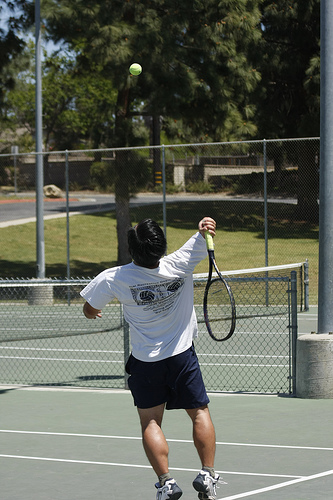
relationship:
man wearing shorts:
[80, 217, 227, 500] [125, 342, 209, 410]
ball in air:
[126, 60, 143, 78] [26, 14, 229, 131]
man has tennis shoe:
[80, 217, 227, 500] [194, 467, 217, 498]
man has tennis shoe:
[80, 217, 227, 500] [147, 473, 181, 498]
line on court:
[251, 412, 299, 466] [17, 397, 115, 495]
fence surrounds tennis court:
[0, 267, 330, 384] [0, 385, 332, 496]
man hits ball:
[80, 217, 227, 500] [113, 43, 160, 86]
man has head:
[80, 217, 227, 500] [120, 207, 190, 263]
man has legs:
[80, 217, 227, 500] [132, 387, 225, 498]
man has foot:
[74, 220, 270, 498] [184, 459, 231, 499]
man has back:
[74, 220, 270, 498] [117, 272, 194, 358]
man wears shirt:
[80, 217, 227, 500] [78, 234, 213, 362]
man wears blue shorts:
[80, 217, 227, 500] [117, 342, 216, 411]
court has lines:
[1, 299, 331, 498] [0, 426, 331, 480]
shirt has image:
[79, 232, 210, 364] [129, 277, 187, 318]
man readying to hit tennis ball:
[80, 217, 227, 500] [122, 59, 154, 78]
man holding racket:
[80, 217, 227, 500] [203, 230, 236, 341]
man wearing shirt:
[80, 217, 227, 500] [78, 234, 213, 362]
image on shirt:
[129, 277, 187, 318] [105, 252, 236, 359]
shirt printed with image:
[86, 238, 241, 375] [133, 280, 180, 301]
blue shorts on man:
[125, 340, 210, 410] [80, 217, 227, 500]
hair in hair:
[127, 218, 167, 266] [131, 227, 140, 242]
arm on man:
[170, 214, 220, 278] [30, 186, 316, 482]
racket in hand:
[198, 227, 244, 340] [192, 210, 221, 238]